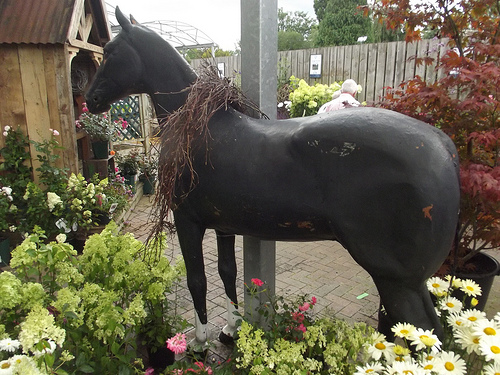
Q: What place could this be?
A: It is a garden.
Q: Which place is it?
A: It is a garden.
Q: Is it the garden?
A: Yes, it is the garden.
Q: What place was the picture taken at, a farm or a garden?
A: It was taken at a garden.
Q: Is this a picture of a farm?
A: No, the picture is showing a garden.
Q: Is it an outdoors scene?
A: Yes, it is outdoors.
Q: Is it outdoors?
A: Yes, it is outdoors.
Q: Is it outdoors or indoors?
A: It is outdoors.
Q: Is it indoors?
A: No, it is outdoors.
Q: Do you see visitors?
A: No, there are no visitors.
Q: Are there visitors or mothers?
A: No, there are no visitors or mothers.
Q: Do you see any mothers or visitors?
A: No, there are no visitors or mothers.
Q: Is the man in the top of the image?
A: Yes, the man is in the top of the image.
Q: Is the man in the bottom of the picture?
A: No, the man is in the top of the image.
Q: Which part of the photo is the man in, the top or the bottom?
A: The man is in the top of the image.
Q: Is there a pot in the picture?
A: Yes, there is a pot.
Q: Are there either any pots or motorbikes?
A: Yes, there is a pot.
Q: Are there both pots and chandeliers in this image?
A: No, there is a pot but no chandeliers.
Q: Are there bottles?
A: No, there are no bottles.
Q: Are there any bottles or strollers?
A: No, there are no bottles or strollers.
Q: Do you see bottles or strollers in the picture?
A: No, there are no bottles or strollers.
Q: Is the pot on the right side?
A: Yes, the pot is on the right of the image.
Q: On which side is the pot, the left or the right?
A: The pot is on the right of the image.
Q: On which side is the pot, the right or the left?
A: The pot is on the right of the image.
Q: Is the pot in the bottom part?
A: Yes, the pot is in the bottom of the image.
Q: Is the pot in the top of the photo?
A: No, the pot is in the bottom of the image.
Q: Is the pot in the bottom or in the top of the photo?
A: The pot is in the bottom of the image.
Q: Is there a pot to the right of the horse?
A: Yes, there is a pot to the right of the horse.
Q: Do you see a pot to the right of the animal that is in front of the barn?
A: Yes, there is a pot to the right of the horse.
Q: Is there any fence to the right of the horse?
A: No, there is a pot to the right of the horse.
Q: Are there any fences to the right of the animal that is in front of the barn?
A: No, there is a pot to the right of the horse.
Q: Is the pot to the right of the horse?
A: Yes, the pot is to the right of the horse.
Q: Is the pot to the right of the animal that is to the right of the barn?
A: Yes, the pot is to the right of the horse.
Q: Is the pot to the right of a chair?
A: No, the pot is to the right of the horse.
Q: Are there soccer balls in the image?
A: No, there are no soccer balls.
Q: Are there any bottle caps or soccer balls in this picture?
A: No, there are no soccer balls or bottle caps.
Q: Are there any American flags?
A: No, there are no American flags.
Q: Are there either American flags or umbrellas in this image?
A: No, there are no American flags or umbrellas.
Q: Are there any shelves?
A: No, there are no shelves.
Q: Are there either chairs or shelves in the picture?
A: No, there are no shelves or chairs.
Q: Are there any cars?
A: No, there are no cars.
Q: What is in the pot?
A: The tree is in the pot.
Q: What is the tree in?
A: The tree is in the pot.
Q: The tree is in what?
A: The tree is in the pot.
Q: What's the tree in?
A: The tree is in the pot.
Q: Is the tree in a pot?
A: Yes, the tree is in a pot.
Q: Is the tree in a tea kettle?
A: No, the tree is in a pot.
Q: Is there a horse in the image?
A: Yes, there is a horse.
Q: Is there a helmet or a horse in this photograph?
A: Yes, there is a horse.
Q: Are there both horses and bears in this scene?
A: No, there is a horse but no bears.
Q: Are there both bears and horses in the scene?
A: No, there is a horse but no bears.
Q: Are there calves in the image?
A: No, there are no calves.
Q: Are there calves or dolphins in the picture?
A: No, there are no calves or dolphins.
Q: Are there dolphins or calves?
A: No, there are no calves or dolphins.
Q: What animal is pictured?
A: The animal is a horse.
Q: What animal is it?
A: The animal is a horse.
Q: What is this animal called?
A: This is a horse.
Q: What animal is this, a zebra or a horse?
A: This is a horse.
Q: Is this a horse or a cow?
A: This is a horse.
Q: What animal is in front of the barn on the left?
A: The horse is in front of the barn.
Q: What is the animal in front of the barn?
A: The animal is a horse.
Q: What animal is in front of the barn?
A: The animal is a horse.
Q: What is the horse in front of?
A: The horse is in front of the barn.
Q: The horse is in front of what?
A: The horse is in front of the barn.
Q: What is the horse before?
A: The horse is in front of the barn.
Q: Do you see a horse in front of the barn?
A: Yes, there is a horse in front of the barn.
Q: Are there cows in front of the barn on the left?
A: No, there is a horse in front of the barn.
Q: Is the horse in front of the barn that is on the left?
A: Yes, the horse is in front of the barn.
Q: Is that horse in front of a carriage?
A: No, the horse is in front of the barn.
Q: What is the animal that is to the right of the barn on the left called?
A: The animal is a horse.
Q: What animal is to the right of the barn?
A: The animal is a horse.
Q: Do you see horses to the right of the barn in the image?
A: Yes, there is a horse to the right of the barn.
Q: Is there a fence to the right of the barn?
A: No, there is a horse to the right of the barn.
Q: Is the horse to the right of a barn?
A: Yes, the horse is to the right of a barn.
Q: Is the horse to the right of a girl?
A: No, the horse is to the right of a barn.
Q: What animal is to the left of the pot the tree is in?
A: The animal is a horse.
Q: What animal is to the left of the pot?
A: The animal is a horse.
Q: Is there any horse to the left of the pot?
A: Yes, there is a horse to the left of the pot.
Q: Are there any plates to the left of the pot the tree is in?
A: No, there is a horse to the left of the pot.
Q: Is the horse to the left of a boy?
A: No, the horse is to the left of the pot.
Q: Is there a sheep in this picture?
A: No, there is no sheep.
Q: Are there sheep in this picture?
A: No, there are no sheep.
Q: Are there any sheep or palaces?
A: No, there are no sheep or palaces.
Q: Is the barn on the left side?
A: Yes, the barn is on the left of the image.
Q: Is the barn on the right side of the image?
A: No, the barn is on the left of the image.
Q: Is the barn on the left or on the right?
A: The barn is on the left of the image.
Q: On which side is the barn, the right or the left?
A: The barn is on the left of the image.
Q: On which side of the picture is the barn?
A: The barn is on the left of the image.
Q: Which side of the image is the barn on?
A: The barn is on the left of the image.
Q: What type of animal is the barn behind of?
A: The barn is behind the horse.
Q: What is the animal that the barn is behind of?
A: The animal is a horse.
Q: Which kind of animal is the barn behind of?
A: The barn is behind the horse.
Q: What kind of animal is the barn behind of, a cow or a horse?
A: The barn is behind a horse.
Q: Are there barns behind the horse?
A: Yes, there is a barn behind the horse.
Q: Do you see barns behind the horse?
A: Yes, there is a barn behind the horse.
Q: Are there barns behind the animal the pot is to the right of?
A: Yes, there is a barn behind the horse.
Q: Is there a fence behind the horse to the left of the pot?
A: No, there is a barn behind the horse.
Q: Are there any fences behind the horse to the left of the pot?
A: No, there is a barn behind the horse.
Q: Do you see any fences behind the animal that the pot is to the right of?
A: No, there is a barn behind the horse.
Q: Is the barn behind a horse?
A: Yes, the barn is behind a horse.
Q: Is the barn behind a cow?
A: No, the barn is behind a horse.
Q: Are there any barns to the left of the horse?
A: Yes, there is a barn to the left of the horse.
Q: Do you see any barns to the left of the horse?
A: Yes, there is a barn to the left of the horse.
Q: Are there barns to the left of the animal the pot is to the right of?
A: Yes, there is a barn to the left of the horse.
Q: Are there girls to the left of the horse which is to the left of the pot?
A: No, there is a barn to the left of the horse.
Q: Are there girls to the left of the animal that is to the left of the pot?
A: No, there is a barn to the left of the horse.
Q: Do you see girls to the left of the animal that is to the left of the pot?
A: No, there is a barn to the left of the horse.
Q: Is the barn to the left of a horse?
A: Yes, the barn is to the left of a horse.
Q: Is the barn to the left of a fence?
A: No, the barn is to the left of a horse.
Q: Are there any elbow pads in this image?
A: No, there are no elbow pads.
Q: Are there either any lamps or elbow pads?
A: No, there are no elbow pads or lamps.